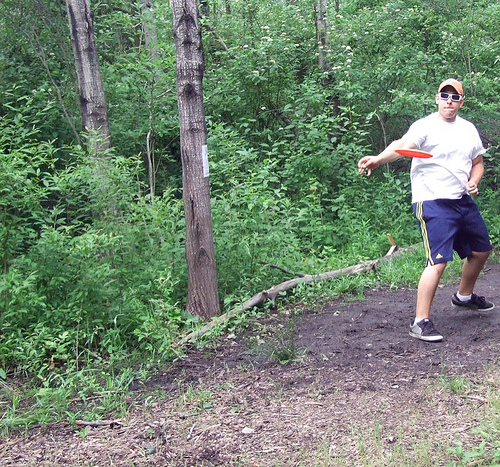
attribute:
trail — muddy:
[0, 262, 499, 465]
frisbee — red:
[391, 146, 437, 159]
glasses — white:
[434, 90, 467, 102]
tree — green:
[57, 0, 131, 318]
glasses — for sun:
[438, 89, 467, 104]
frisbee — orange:
[388, 133, 459, 171]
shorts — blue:
[403, 187, 498, 274]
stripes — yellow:
[399, 187, 436, 284]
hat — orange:
[430, 73, 462, 90]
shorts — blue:
[356, 62, 496, 264]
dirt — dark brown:
[1, 259, 499, 464]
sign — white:
[200, 140, 212, 177]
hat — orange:
[424, 59, 473, 106]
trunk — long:
[144, 25, 245, 302]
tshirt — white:
[401, 107, 486, 202]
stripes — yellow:
[415, 197, 434, 265]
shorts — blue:
[410, 192, 492, 264]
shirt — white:
[404, 111, 488, 202]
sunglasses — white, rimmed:
[436, 91, 466, 101]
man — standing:
[340, 70, 497, 340]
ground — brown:
[3, 270, 496, 465]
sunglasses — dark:
[418, 66, 468, 121]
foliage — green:
[1, 3, 498, 460]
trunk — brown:
[171, 6, 222, 323]